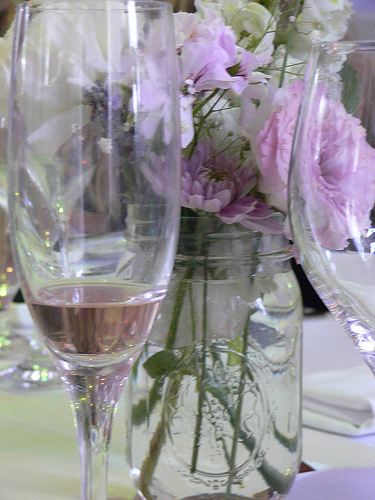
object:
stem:
[64, 370, 121, 498]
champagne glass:
[7, 0, 182, 499]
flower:
[129, 8, 254, 136]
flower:
[137, 136, 286, 234]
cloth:
[0, 288, 375, 500]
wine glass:
[288, 38, 375, 365]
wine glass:
[14, 349, 65, 386]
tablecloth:
[274, 462, 375, 498]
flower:
[150, 165, 288, 235]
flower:
[198, 4, 241, 21]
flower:
[251, 78, 373, 249]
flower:
[226, 0, 269, 30]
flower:
[298, 0, 353, 39]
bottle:
[116, 190, 304, 500]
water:
[173, 470, 184, 489]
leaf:
[142, 348, 177, 379]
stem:
[132, 214, 204, 426]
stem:
[187, 235, 212, 474]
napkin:
[296, 359, 374, 433]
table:
[2, 306, 373, 498]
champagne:
[22, 284, 167, 387]